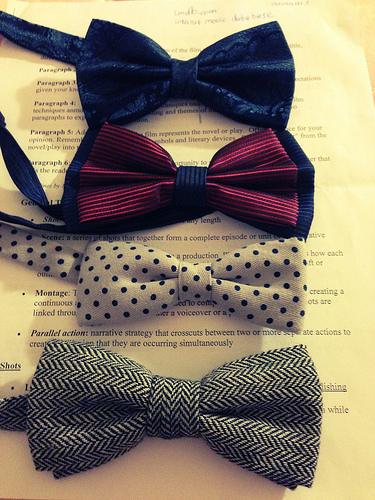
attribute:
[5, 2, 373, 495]
paper — under, typed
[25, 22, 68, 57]
fabric — blue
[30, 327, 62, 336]
word — written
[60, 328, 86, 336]
word — written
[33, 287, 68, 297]
word — written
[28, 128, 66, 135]
word — written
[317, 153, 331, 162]
word — written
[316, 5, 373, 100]
part — folded